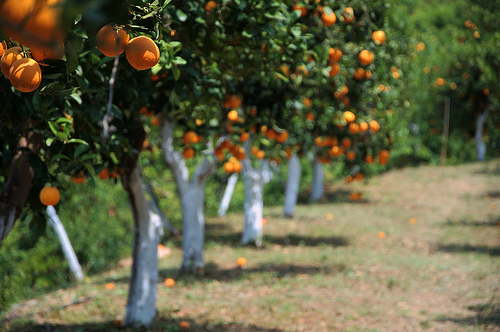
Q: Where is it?
A: This is at the garden.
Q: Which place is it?
A: It is a garden.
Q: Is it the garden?
A: Yes, it is the garden.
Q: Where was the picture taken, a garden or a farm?
A: It was taken at a garden.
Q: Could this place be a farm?
A: No, it is a garden.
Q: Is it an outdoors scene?
A: Yes, it is outdoors.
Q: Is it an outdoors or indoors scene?
A: It is outdoors.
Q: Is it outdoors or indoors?
A: It is outdoors.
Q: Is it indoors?
A: No, it is outdoors.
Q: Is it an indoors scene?
A: No, it is outdoors.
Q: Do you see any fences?
A: No, there are no fences.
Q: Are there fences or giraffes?
A: No, there are no fences or giraffes.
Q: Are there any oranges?
A: Yes, there are oranges.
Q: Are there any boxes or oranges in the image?
A: Yes, there are oranges.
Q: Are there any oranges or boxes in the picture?
A: Yes, there are oranges.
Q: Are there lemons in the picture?
A: No, there are no lemons.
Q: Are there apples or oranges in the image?
A: Yes, there are oranges.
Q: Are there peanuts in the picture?
A: No, there are no peanuts.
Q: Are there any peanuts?
A: No, there are no peanuts.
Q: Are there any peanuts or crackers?
A: No, there are no peanuts or crackers.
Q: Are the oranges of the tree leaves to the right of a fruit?
A: No, the oranges are to the left of a fruit.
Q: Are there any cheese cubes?
A: No, there are no cheese cubes.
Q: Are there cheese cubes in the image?
A: No, there are no cheese cubes.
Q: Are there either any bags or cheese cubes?
A: No, there are no cheese cubes or bags.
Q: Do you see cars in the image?
A: No, there are no cars.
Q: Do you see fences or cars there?
A: No, there are no cars or fences.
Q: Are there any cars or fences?
A: No, there are no cars or fences.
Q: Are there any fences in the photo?
A: No, there are no fences.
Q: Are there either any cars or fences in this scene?
A: No, there are no fences or cars.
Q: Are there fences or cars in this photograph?
A: No, there are no fences or cars.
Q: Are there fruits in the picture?
A: Yes, there is a fruit.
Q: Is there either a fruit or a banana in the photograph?
A: Yes, there is a fruit.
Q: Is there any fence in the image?
A: No, there are no fences.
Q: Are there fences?
A: No, there are no fences.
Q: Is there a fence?
A: No, there are no fences.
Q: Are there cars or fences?
A: No, there are no fences or cars.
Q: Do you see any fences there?
A: No, there are no fences.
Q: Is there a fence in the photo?
A: No, there are no fences.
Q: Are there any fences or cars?
A: No, there are no fences or cars.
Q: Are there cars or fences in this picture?
A: No, there are no fences or cars.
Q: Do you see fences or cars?
A: No, there are no fences or cars.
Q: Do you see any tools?
A: No, there are no tools.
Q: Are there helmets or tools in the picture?
A: No, there are no tools or helmets.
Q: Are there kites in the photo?
A: No, there are no kites.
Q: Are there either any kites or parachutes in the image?
A: No, there are no kites or parachutes.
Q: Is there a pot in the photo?
A: No, there are no pots.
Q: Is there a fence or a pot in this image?
A: No, there are no pots or fences.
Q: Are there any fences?
A: No, there are no fences.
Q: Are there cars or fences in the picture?
A: No, there are no fences or cars.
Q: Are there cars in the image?
A: No, there are no cars.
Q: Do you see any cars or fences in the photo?
A: No, there are no cars or fences.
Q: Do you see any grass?
A: Yes, there is grass.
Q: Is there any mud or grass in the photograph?
A: Yes, there is grass.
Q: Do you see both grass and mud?
A: No, there is grass but no mud.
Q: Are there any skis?
A: No, there are no skis.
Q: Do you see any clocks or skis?
A: No, there are no skis or clocks.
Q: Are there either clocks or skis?
A: No, there are no skis or clocks.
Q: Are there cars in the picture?
A: No, there are no cars.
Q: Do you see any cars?
A: No, there are no cars.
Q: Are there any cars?
A: No, there are no cars.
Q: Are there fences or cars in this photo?
A: No, there are no cars or fences.